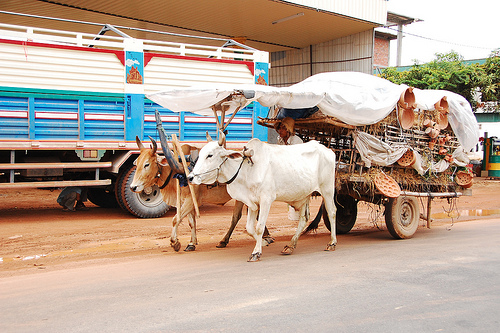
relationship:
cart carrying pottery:
[319, 62, 498, 243] [402, 86, 415, 128]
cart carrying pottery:
[319, 62, 498, 243] [434, 97, 447, 126]